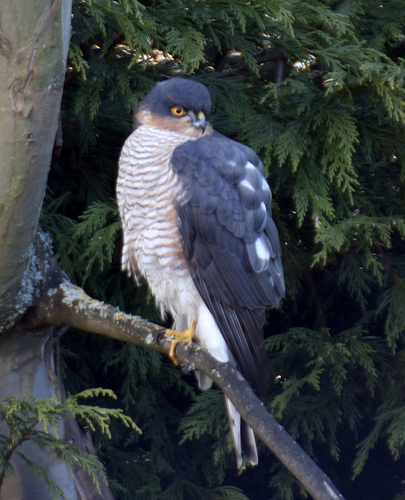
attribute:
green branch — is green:
[0, 385, 138, 498]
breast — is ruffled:
[117, 150, 201, 246]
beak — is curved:
[192, 111, 207, 130]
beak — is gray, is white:
[194, 110, 207, 134]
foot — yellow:
[159, 320, 207, 363]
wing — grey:
[172, 126, 288, 313]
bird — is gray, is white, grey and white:
[111, 77, 289, 472]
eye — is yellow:
[160, 98, 188, 125]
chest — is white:
[110, 125, 186, 272]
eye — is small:
[172, 103, 188, 120]